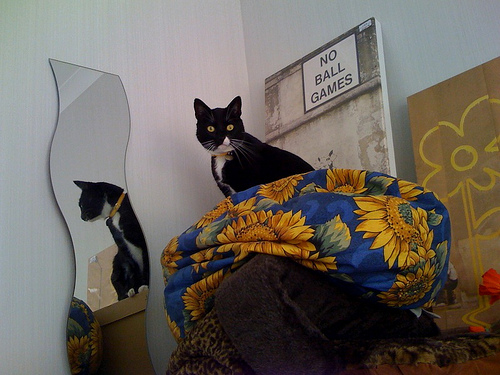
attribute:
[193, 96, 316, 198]
cat — black, white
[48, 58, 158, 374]
mirror — clear, curvy, long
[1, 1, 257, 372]
wall — white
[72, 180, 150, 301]
reflection of cat — black, white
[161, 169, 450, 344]
blanket — blue, yellow, gold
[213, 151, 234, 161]
collar — yellow, orange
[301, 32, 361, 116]
sign — black, white, small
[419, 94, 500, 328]
flower — yellow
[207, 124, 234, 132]
eyes — yellow, green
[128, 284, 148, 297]
paws — white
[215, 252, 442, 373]
pillow — dark brown